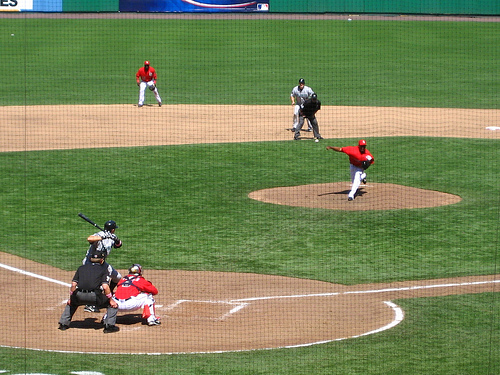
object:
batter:
[76, 211, 124, 266]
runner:
[289, 76, 322, 134]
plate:
[290, 124, 316, 135]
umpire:
[55, 249, 124, 335]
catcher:
[104, 261, 160, 329]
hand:
[323, 144, 332, 152]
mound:
[245, 171, 463, 215]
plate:
[104, 290, 160, 313]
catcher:
[135, 66, 159, 84]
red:
[135, 66, 157, 86]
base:
[483, 124, 499, 135]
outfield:
[0, 0, 499, 113]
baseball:
[314, 136, 320, 143]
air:
[0, 0, 498, 374]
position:
[100, 262, 160, 326]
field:
[0, 5, 496, 375]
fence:
[6, 0, 499, 31]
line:
[0, 260, 500, 316]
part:
[2, 248, 75, 300]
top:
[346, 143, 379, 169]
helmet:
[99, 217, 124, 233]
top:
[71, 261, 114, 293]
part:
[0, 84, 499, 155]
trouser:
[115, 293, 156, 331]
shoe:
[145, 316, 164, 324]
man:
[326, 138, 377, 201]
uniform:
[80, 230, 125, 266]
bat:
[78, 212, 109, 233]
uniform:
[292, 87, 316, 125]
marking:
[159, 292, 245, 325]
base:
[97, 285, 242, 330]